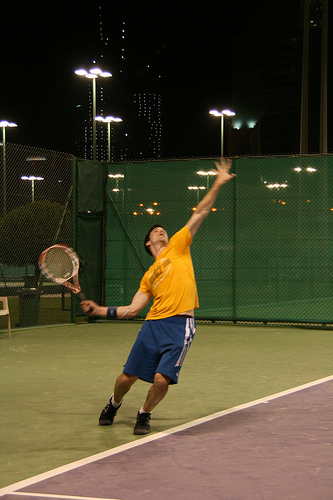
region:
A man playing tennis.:
[34, 114, 269, 459]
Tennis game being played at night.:
[11, 12, 323, 488]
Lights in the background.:
[0, 43, 311, 212]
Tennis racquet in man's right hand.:
[37, 240, 107, 324]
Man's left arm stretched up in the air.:
[112, 147, 238, 423]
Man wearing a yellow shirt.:
[124, 214, 203, 323]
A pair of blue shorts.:
[120, 315, 200, 383]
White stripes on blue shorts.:
[120, 314, 193, 382]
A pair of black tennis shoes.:
[98, 398, 152, 433]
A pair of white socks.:
[101, 387, 163, 415]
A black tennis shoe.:
[131, 407, 153, 435]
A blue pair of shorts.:
[122, 314, 197, 384]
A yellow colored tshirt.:
[138, 223, 201, 322]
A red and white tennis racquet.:
[39, 241, 87, 304]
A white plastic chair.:
[0, 295, 14, 342]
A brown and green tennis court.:
[0, 318, 332, 498]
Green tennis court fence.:
[103, 153, 222, 317]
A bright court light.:
[94, 111, 125, 159]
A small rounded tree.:
[0, 197, 70, 285]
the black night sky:
[179, 10, 301, 114]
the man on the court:
[19, 144, 258, 446]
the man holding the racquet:
[32, 153, 255, 443]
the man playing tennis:
[25, 102, 231, 498]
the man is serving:
[30, 148, 230, 440]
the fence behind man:
[5, 145, 81, 322]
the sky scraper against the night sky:
[62, 2, 178, 153]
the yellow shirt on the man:
[118, 230, 222, 321]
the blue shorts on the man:
[124, 315, 196, 387]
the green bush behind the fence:
[4, 202, 78, 258]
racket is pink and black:
[33, 240, 94, 317]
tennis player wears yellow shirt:
[66, 147, 245, 441]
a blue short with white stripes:
[119, 312, 198, 384]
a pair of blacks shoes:
[94, 396, 152, 436]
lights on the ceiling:
[10, 140, 327, 202]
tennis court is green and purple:
[0, 315, 332, 499]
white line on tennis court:
[0, 358, 328, 493]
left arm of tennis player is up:
[64, 153, 260, 351]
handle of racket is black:
[74, 286, 98, 315]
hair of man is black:
[136, 218, 204, 279]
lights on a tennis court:
[53, 56, 330, 195]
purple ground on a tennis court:
[202, 388, 310, 493]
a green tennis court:
[26, 345, 123, 493]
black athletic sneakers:
[79, 385, 182, 446]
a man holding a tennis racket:
[36, 191, 174, 329]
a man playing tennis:
[35, 173, 283, 476]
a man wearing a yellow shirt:
[74, 172, 198, 308]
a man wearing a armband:
[68, 190, 205, 339]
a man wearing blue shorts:
[92, 224, 219, 395]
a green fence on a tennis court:
[46, 149, 327, 328]